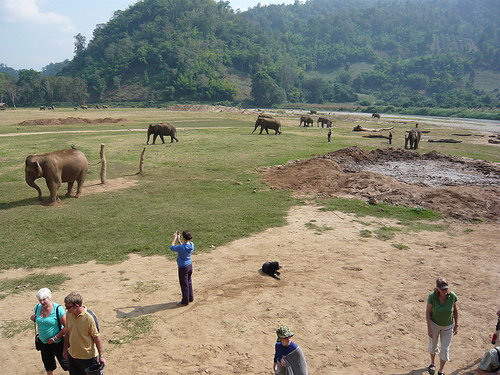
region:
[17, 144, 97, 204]
Elephant standing in field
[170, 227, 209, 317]
Woman taking a picture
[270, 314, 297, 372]
Boy with a hat on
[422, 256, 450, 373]
Woman wearing a green shirt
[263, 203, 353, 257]
Ground with no grass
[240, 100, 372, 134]
Group of elephants walking in field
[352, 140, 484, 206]
Dried up watering hole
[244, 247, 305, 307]
Dog laying in the dirt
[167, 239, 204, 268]
Woman is wearing a blue shirt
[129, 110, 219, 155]
Elephant is touching the grass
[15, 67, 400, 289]
elephant standing in grass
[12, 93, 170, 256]
elephants standing on grass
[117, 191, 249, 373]
a women taking a picture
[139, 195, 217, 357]
a women standing in dirt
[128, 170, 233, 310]
a woman wearing a blue shirt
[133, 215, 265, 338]
a woman with her hair up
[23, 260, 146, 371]
an older couple together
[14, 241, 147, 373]
an older couple walking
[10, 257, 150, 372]
an older couple in the field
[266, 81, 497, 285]
a pile of mud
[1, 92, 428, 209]
Elephants in the field.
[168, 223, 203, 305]
Woman taking pictures.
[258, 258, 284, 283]
Animal laying down on ground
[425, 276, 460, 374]
Woman with visor on.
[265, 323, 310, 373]
Person with a hat on.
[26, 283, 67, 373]
Woman with white hair walking away.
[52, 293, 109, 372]
Man with sunglasses on.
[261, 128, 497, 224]
Muddy area near the elephants.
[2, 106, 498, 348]
Grassy area with elephants.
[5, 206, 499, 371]
Dirt area with the elephants.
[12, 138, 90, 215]
elephant pointed toward left of photo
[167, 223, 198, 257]
woman in blue taking photo with camera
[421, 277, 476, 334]
woman in green wearing brown hat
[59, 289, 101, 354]
man in yellow shirt wearing dark glasses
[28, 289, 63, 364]
woman in light blue with two straps over each arm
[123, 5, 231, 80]
dark green trees located in back of picture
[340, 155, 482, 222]
dark brown mudhole on right of photo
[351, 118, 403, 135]
large broken piece of tree on ground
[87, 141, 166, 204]
two wooden tree stumps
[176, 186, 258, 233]
green grass located in the middle of photo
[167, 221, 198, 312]
a woman taking a picture of an elephant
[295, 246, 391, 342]
an area of dirt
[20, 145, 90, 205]
an elephant standing in the grass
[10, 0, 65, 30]
a white fluffy cloud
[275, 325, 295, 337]
a person's hat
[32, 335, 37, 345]
a woman's handbag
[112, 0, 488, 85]
a large area of trees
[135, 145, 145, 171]
a wooden post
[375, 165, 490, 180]
a muddy area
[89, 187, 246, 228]
a grassy area